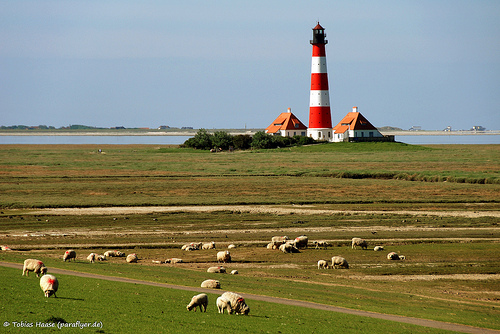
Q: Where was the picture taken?
A: It was taken at the field.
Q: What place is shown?
A: It is a field.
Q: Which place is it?
A: It is a field.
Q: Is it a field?
A: Yes, it is a field.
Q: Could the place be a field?
A: Yes, it is a field.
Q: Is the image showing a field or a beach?
A: It is showing a field.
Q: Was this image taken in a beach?
A: No, the picture was taken in a field.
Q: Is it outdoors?
A: Yes, it is outdoors.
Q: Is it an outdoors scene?
A: Yes, it is outdoors.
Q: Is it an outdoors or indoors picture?
A: It is outdoors.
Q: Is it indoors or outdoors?
A: It is outdoors.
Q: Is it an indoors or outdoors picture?
A: It is outdoors.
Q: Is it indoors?
A: No, it is outdoors.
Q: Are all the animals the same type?
A: Yes, all the animals are sheep.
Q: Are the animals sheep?
A: Yes, all the animals are sheep.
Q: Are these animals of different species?
A: No, all the animals are sheep.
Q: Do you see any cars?
A: No, there are no cars.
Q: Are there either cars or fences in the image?
A: No, there are no cars or fences.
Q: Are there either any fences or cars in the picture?
A: No, there are no cars or fences.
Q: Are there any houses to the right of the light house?
A: Yes, there is a house to the right of the light house.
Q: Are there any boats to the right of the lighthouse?
A: No, there is a house to the right of the lighthouse.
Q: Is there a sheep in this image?
A: Yes, there is a sheep.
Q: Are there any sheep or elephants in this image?
A: Yes, there is a sheep.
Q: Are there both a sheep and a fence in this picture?
A: No, there is a sheep but no fences.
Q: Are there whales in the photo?
A: No, there are no whales.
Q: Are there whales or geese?
A: No, there are no whales or geese.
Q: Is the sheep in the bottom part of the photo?
A: Yes, the sheep is in the bottom of the image.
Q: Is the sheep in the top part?
A: No, the sheep is in the bottom of the image.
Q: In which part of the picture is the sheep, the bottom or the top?
A: The sheep is in the bottom of the image.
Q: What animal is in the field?
A: The animal is a sheep.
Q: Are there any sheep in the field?
A: Yes, there is a sheep in the field.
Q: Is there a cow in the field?
A: No, there is a sheep in the field.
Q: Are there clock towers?
A: No, there are no clock towers.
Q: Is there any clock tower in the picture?
A: No, there are no clock towers.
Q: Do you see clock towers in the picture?
A: No, there are no clock towers.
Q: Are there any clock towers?
A: No, there are no clock towers.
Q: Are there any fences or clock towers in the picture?
A: No, there are no clock towers or fences.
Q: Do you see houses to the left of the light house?
A: Yes, there is a house to the left of the light house.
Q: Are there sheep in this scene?
A: Yes, there is a sheep.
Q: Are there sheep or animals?
A: Yes, there is a sheep.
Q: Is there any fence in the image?
A: No, there are no fences.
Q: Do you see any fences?
A: No, there are no fences.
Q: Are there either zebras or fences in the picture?
A: No, there are no fences or zebras.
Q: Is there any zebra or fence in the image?
A: No, there are no fences or zebras.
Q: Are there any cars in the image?
A: No, there are no cars.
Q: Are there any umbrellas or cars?
A: No, there are no cars or umbrellas.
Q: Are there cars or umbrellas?
A: No, there are no cars or umbrellas.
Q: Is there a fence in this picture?
A: No, there are no fences.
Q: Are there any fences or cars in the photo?
A: No, there are no fences or cars.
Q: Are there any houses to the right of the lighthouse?
A: Yes, there is a house to the right of the lighthouse.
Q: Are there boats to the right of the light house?
A: No, there is a house to the right of the light house.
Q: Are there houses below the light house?
A: Yes, there is a house below the light house.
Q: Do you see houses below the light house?
A: Yes, there is a house below the light house.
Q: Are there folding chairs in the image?
A: No, there are no folding chairs.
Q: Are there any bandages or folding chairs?
A: No, there are no folding chairs or bandages.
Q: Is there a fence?
A: No, there are no fences.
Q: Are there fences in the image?
A: No, there are no fences.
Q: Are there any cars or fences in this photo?
A: No, there are no fences or cars.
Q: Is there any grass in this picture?
A: Yes, there is grass.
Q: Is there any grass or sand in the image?
A: Yes, there is grass.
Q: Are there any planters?
A: No, there are no planters.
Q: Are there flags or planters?
A: No, there are no planters or flags.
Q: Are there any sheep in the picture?
A: Yes, there is a sheep.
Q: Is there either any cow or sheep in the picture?
A: Yes, there is a sheep.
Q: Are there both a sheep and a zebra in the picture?
A: No, there is a sheep but no zebras.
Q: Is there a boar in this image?
A: No, there are no boars.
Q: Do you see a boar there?
A: No, there are no boars.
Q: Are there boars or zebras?
A: No, there are no boars or zebras.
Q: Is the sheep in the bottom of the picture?
A: Yes, the sheep is in the bottom of the image.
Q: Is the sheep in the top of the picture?
A: No, the sheep is in the bottom of the image.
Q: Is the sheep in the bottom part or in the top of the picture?
A: The sheep is in the bottom of the image.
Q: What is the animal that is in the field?
A: The animal is a sheep.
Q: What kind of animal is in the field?
A: The animal is a sheep.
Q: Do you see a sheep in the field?
A: Yes, there is a sheep in the field.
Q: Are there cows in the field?
A: No, there is a sheep in the field.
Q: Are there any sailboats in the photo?
A: No, there are no sailboats.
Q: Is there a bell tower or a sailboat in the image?
A: No, there are no sailboats or bell towers.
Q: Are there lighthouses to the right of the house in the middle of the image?
A: Yes, there is a lighthouse to the right of the house.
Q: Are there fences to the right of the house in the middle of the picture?
A: No, there is a lighthouse to the right of the house.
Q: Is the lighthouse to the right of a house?
A: Yes, the lighthouse is to the right of a house.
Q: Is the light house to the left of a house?
A: Yes, the light house is to the left of a house.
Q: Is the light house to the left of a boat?
A: No, the light house is to the left of a house.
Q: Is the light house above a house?
A: Yes, the light house is above a house.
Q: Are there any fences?
A: No, there are no fences.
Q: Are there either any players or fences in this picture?
A: No, there are no fences or players.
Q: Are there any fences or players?
A: No, there are no fences or players.